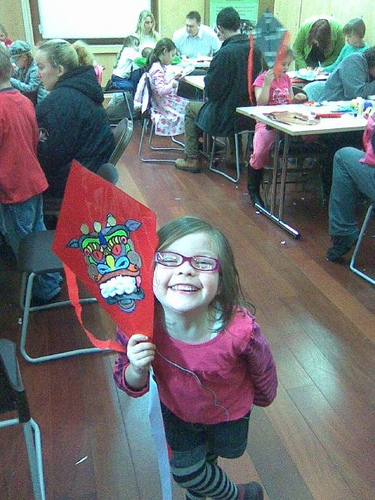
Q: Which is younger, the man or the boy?
A: The boy is younger than the man.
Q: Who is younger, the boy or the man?
A: The boy is younger than the man.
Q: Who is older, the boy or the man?
A: The man is older than the boy.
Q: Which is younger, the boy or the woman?
A: The boy is younger than the woman.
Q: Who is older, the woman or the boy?
A: The woman is older than the boy.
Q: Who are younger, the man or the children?
A: The children are younger than the man.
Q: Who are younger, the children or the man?
A: The children are younger than the man.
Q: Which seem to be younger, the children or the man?
A: The children are younger than the man.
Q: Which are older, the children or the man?
A: The man are older than the children.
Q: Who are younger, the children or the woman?
A: The children are younger than the woman.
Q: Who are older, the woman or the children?
A: The woman are older than the children.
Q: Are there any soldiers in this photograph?
A: No, there are no soldiers.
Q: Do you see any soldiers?
A: No, there are no soldiers.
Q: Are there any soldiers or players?
A: No, there are no soldiers or players.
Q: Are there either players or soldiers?
A: No, there are no soldiers or players.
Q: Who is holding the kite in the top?
A: The girl is holding the kite.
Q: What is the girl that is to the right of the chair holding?
A: The girl is holding the kite.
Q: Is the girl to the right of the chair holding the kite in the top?
A: Yes, the girl is holding the kite.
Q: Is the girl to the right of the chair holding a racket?
A: No, the girl is holding the kite.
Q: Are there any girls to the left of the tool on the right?
A: Yes, there is a girl to the left of the tool.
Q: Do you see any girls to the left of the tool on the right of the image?
A: Yes, there is a girl to the left of the tool.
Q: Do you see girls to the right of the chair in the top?
A: Yes, there is a girl to the right of the chair.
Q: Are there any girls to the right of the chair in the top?
A: Yes, there is a girl to the right of the chair.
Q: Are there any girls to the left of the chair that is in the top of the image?
A: No, the girl is to the right of the chair.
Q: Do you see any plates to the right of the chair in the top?
A: No, there is a girl to the right of the chair.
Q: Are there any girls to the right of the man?
A: Yes, there is a girl to the right of the man.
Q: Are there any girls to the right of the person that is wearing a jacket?
A: Yes, there is a girl to the right of the man.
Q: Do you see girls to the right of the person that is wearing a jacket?
A: Yes, there is a girl to the right of the man.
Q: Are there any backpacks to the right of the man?
A: No, there is a girl to the right of the man.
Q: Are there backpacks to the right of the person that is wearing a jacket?
A: No, there is a girl to the right of the man.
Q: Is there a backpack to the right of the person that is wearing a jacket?
A: No, there is a girl to the right of the man.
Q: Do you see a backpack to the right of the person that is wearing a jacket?
A: No, there is a girl to the right of the man.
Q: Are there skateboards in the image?
A: No, there are no skateboards.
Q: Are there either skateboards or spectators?
A: No, there are no skateboards or spectators.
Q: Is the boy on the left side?
A: Yes, the boy is on the left of the image.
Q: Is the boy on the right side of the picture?
A: No, the boy is on the left of the image.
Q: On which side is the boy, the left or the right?
A: The boy is on the left of the image.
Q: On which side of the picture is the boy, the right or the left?
A: The boy is on the left of the image.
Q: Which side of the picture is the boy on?
A: The boy is on the left of the image.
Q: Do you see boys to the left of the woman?
A: Yes, there is a boy to the left of the woman.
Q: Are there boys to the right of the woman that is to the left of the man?
A: No, the boy is to the left of the woman.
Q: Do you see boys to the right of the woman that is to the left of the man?
A: No, the boy is to the left of the woman.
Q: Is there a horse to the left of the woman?
A: No, there is a boy to the left of the woman.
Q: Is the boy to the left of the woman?
A: Yes, the boy is to the left of the woman.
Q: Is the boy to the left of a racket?
A: No, the boy is to the left of the woman.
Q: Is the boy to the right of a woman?
A: No, the boy is to the left of a woman.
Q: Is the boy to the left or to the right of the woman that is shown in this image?
A: The boy is to the left of the woman.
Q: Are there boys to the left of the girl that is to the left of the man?
A: Yes, there is a boy to the left of the girl.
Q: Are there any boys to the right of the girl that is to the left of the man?
A: No, the boy is to the left of the girl.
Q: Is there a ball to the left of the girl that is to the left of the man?
A: No, there is a boy to the left of the girl.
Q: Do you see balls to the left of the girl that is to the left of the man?
A: No, there is a boy to the left of the girl.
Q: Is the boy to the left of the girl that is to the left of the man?
A: Yes, the boy is to the left of the girl.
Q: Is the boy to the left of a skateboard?
A: No, the boy is to the left of the girl.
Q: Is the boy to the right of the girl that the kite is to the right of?
A: No, the boy is to the left of the girl.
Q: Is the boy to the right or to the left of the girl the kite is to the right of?
A: The boy is to the left of the girl.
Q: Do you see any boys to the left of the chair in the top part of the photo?
A: Yes, there is a boy to the left of the chair.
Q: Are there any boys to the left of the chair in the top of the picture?
A: Yes, there is a boy to the left of the chair.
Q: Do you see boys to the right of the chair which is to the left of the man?
A: No, the boy is to the left of the chair.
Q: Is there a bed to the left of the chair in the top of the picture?
A: No, there is a boy to the left of the chair.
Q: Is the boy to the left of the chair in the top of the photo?
A: Yes, the boy is to the left of the chair.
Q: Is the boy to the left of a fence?
A: No, the boy is to the left of the chair.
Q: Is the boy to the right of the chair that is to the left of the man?
A: No, the boy is to the left of the chair.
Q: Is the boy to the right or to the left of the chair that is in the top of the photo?
A: The boy is to the left of the chair.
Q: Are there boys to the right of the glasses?
A: No, the boy is to the left of the glasses.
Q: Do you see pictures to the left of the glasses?
A: No, there is a boy to the left of the glasses.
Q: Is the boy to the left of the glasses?
A: Yes, the boy is to the left of the glasses.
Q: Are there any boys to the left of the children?
A: Yes, there is a boy to the left of the children.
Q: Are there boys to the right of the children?
A: No, the boy is to the left of the children.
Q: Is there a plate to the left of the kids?
A: No, there is a boy to the left of the kids.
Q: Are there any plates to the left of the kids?
A: No, there is a boy to the left of the kids.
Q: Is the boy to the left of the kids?
A: Yes, the boy is to the left of the kids.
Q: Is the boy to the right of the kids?
A: No, the boy is to the left of the kids.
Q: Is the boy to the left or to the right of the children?
A: The boy is to the left of the children.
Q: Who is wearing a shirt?
A: The boy is wearing a shirt.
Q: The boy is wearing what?
A: The boy is wearing a shirt.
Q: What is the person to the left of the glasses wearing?
A: The boy is wearing a shirt.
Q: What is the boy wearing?
A: The boy is wearing a shirt.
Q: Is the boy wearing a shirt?
A: Yes, the boy is wearing a shirt.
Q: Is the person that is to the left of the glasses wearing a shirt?
A: Yes, the boy is wearing a shirt.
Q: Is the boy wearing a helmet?
A: No, the boy is wearing a shirt.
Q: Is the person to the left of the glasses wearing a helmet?
A: No, the boy is wearing a shirt.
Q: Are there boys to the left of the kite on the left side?
A: Yes, there is a boy to the left of the kite.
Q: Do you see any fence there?
A: No, there are no fences.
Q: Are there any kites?
A: Yes, there is a kite.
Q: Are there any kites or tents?
A: Yes, there is a kite.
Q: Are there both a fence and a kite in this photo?
A: No, there is a kite but no fences.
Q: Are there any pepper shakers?
A: No, there are no pepper shakers.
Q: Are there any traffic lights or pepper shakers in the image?
A: No, there are no pepper shakers or traffic lights.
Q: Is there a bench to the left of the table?
A: No, there is a kite to the left of the table.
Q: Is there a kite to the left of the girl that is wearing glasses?
A: Yes, there is a kite to the left of the girl.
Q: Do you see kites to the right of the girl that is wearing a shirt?
A: No, the kite is to the left of the girl.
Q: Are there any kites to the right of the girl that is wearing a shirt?
A: No, the kite is to the left of the girl.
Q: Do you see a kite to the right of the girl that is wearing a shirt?
A: No, the kite is to the left of the girl.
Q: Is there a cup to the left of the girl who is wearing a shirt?
A: No, there is a kite to the left of the girl.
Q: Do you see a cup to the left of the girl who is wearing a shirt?
A: No, there is a kite to the left of the girl.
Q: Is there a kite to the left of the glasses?
A: Yes, there is a kite to the left of the glasses.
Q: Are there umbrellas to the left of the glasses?
A: No, there is a kite to the left of the glasses.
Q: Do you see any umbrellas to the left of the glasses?
A: No, there is a kite to the left of the glasses.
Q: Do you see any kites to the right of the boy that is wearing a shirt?
A: Yes, there is a kite to the right of the boy.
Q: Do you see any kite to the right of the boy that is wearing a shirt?
A: Yes, there is a kite to the right of the boy.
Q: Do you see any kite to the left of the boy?
A: No, the kite is to the right of the boy.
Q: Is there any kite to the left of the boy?
A: No, the kite is to the right of the boy.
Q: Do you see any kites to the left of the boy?
A: No, the kite is to the right of the boy.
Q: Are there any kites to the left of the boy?
A: No, the kite is to the right of the boy.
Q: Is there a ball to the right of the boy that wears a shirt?
A: No, there is a kite to the right of the boy.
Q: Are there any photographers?
A: No, there are no photographers.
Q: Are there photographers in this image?
A: No, there are no photographers.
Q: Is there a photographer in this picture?
A: No, there are no photographers.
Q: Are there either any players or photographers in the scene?
A: No, there are no photographers or players.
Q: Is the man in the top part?
A: Yes, the man is in the top of the image.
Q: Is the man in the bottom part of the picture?
A: No, the man is in the top of the image.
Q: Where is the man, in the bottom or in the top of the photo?
A: The man is in the top of the image.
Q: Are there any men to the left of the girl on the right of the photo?
A: Yes, there is a man to the left of the girl.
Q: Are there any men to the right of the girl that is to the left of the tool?
A: No, the man is to the left of the girl.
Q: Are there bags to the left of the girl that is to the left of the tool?
A: No, there is a man to the left of the girl.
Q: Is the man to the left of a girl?
A: Yes, the man is to the left of a girl.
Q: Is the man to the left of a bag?
A: No, the man is to the left of a girl.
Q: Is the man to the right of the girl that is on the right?
A: No, the man is to the left of the girl.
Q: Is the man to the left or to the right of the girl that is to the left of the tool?
A: The man is to the left of the girl.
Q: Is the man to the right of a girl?
A: Yes, the man is to the right of a girl.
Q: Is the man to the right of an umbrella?
A: No, the man is to the right of a girl.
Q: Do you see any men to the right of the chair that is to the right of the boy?
A: Yes, there is a man to the right of the chair.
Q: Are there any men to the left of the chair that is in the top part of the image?
A: No, the man is to the right of the chair.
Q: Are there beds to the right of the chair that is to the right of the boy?
A: No, there is a man to the right of the chair.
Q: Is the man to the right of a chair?
A: Yes, the man is to the right of a chair.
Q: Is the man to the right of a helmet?
A: No, the man is to the right of a chair.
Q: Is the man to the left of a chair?
A: No, the man is to the right of a chair.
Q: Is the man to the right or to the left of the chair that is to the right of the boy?
A: The man is to the right of the chair.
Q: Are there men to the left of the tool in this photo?
A: Yes, there is a man to the left of the tool.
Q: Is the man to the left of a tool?
A: Yes, the man is to the left of a tool.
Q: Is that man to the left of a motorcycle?
A: No, the man is to the left of a tool.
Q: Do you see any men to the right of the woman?
A: Yes, there is a man to the right of the woman.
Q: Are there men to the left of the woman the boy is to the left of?
A: No, the man is to the right of the woman.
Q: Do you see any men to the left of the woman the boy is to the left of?
A: No, the man is to the right of the woman.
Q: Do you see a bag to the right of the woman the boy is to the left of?
A: No, there is a man to the right of the woman.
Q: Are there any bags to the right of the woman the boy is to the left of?
A: No, there is a man to the right of the woman.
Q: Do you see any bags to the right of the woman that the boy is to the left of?
A: No, there is a man to the right of the woman.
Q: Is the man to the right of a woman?
A: Yes, the man is to the right of a woman.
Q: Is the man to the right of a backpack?
A: No, the man is to the right of a woman.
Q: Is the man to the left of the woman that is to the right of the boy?
A: No, the man is to the right of the woman.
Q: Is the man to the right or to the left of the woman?
A: The man is to the right of the woman.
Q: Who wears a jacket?
A: The man wears a jacket.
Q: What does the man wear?
A: The man wears a jacket.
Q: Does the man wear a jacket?
A: Yes, the man wears a jacket.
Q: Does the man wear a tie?
A: No, the man wears a jacket.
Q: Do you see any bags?
A: No, there are no bags.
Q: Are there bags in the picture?
A: No, there are no bags.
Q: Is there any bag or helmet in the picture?
A: No, there are no bags or helmets.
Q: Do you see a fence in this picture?
A: No, there are no fences.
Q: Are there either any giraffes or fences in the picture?
A: No, there are no fences or giraffes.